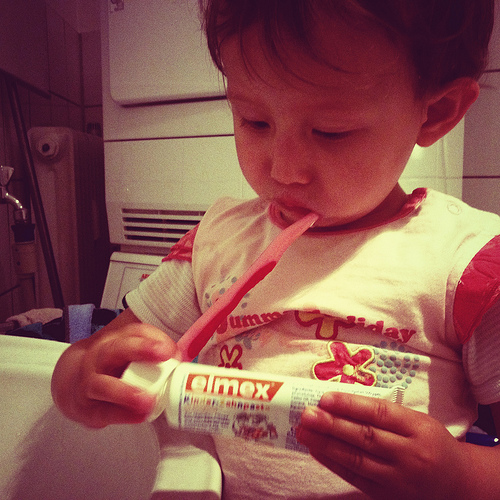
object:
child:
[51, 1, 500, 498]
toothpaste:
[119, 356, 404, 457]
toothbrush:
[175, 212, 320, 365]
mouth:
[268, 194, 321, 223]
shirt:
[125, 196, 499, 497]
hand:
[73, 324, 174, 429]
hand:
[296, 393, 464, 495]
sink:
[3, 334, 158, 499]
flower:
[314, 341, 377, 388]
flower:
[219, 346, 244, 369]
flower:
[294, 308, 354, 341]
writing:
[181, 373, 274, 399]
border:
[292, 311, 356, 338]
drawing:
[232, 413, 277, 444]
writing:
[217, 305, 418, 345]